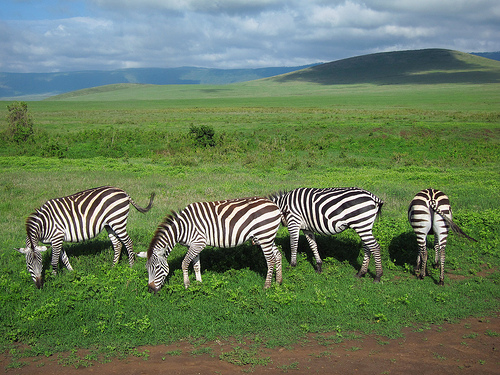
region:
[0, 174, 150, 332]
a zebra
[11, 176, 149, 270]
black and white zebra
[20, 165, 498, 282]
four zebras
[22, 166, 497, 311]
a bunch of zebras grazing in the grass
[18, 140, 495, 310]
four zebras eating grass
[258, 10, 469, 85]
a small hill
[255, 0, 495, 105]
a cloud hovering over a small hill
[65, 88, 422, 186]
green grass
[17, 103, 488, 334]
a bunch of zebras standing in the grass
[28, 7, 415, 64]
clouds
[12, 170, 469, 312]
a group of zebras in a field.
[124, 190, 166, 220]
the tail of the zebra on the zebra at the fat left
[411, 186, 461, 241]
the behind of a zebra on the far right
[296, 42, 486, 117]
a low hill in the distance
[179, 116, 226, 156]
a lone green tree in the field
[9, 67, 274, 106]
rolling low hills in the distance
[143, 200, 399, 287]
two zebras next to each other facing to the left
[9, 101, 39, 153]
another lone tree in the field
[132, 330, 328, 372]
a dirt path in front of the zebras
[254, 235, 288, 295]
the back legs of one of the middle zebras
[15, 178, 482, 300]
Zebras grazing on the plain.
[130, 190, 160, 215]
A zebra's wagging tail.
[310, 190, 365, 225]
A zebra's black and white stripes.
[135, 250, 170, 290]
A zebra's horse-like head.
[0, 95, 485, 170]
Trees and scrub bush on the plain.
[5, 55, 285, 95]
Blue colored mountains in the distance.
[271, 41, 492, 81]
A hill on the plain.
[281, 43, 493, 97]
Shadow of a cloud on the hill.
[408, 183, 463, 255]
A zebra's black and white hindquarters.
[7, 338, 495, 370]
Reddish brown clay on the plain.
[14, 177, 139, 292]
The zebra on the left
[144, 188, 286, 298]
The zebra that is second from the left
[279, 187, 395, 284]
The zebra that is second from the right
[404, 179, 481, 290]
The zebra on the right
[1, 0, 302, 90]
The sky to the left of the hill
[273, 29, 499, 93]
The hill in the upper right hand corner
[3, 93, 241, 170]
The bushes in the middle, to the left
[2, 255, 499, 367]
The grass that the zebras are grazing on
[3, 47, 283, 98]
Hills off in the distance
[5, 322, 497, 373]
A dirt path or road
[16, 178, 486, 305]
a group of four zebras on a savanna.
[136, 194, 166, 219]
the tail on one of the zebras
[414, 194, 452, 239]
the rear end of the zebra on the right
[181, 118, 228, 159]
a small green tree on the savanna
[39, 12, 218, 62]
white clouds in the sky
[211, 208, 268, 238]
stripes on the side of the zebra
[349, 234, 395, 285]
the back legs of the zebra in the middle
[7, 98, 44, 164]
a tree in the middle of the savanna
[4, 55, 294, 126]
low rolling hills in the distance